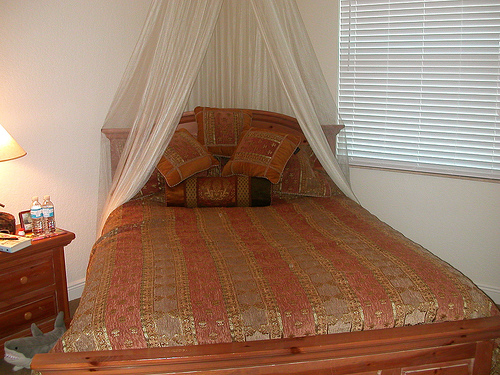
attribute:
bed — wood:
[31, 101, 500, 374]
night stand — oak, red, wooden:
[0, 227, 77, 356]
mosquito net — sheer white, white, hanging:
[93, 0, 361, 239]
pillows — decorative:
[111, 106, 345, 207]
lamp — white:
[2, 130, 28, 233]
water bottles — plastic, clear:
[31, 194, 59, 238]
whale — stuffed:
[4, 310, 67, 371]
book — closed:
[0, 232, 33, 254]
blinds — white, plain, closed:
[336, 0, 500, 183]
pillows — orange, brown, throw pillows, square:
[156, 106, 303, 187]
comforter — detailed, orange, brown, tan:
[48, 191, 500, 353]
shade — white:
[1, 126, 26, 163]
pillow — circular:
[163, 175, 272, 206]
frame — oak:
[102, 117, 345, 195]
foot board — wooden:
[31, 316, 496, 375]